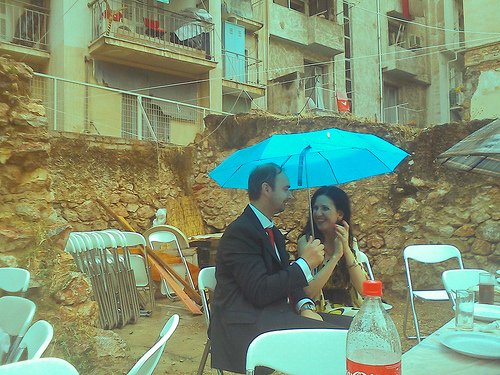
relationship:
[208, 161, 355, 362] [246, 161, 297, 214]
man has head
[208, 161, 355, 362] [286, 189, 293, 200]
man has nose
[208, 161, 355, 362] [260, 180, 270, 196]
man has ear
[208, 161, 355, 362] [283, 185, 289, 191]
man has eye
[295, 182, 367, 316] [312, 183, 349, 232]
woman has head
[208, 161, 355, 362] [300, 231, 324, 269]
man has hand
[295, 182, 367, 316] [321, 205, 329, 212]
woman has eye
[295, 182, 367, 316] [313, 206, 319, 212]
woman has eye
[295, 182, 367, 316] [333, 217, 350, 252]
woman has hand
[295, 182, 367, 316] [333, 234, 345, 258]
woman has hand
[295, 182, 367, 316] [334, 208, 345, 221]
woman has ear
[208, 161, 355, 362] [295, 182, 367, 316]
man next to woman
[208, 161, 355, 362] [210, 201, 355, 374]
man wearing suit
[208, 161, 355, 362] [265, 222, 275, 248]
man wearing tie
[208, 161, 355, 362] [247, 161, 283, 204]
man has hair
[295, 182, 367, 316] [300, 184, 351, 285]
woman has hair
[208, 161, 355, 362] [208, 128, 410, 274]
man holding umbrella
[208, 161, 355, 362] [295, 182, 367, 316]
man looking at woman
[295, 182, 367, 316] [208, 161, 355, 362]
woman smiling at man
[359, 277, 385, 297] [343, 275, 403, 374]
cap on top of bottle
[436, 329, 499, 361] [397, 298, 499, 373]
plate on top of table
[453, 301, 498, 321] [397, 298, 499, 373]
plate on top of table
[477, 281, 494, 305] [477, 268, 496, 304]
liquid inside of glass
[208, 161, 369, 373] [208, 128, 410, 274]
couple underneath umbrella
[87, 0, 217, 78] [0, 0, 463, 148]
balcony on side of building